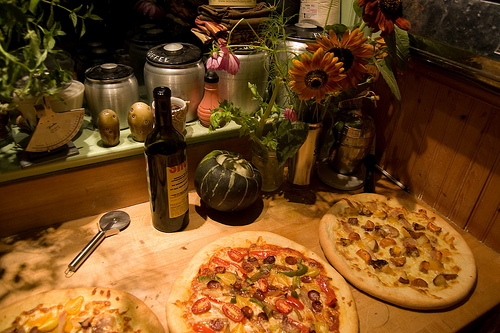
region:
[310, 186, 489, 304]
pizza on a counter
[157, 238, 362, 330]
pizza on a counter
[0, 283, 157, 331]
pizza on a counter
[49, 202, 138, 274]
pizza cutter on the counter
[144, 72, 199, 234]
bottle on the counter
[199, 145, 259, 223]
squash on the counter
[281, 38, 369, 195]
flowers in a vase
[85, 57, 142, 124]
canister on a ledge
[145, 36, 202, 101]
canister on a ledge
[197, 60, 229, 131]
pink bottle on a ledge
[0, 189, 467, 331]
Three pizzas on wooden surface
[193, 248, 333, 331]
Tomato toppings on pizza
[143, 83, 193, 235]
A green colored bottle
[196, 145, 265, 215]
Green pumpkin beside bottle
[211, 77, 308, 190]
A glass with plants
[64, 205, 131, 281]
Silver spoon on counter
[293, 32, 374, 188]
Sunflowers in a vase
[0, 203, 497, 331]
Brown counter made of wood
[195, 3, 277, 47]
Folded clothes on a vase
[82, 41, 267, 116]
Black and silver vases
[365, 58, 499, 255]
wood paneling on wall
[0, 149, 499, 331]
wooden counter-top touching walls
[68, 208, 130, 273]
a silver colored metal pizza cutter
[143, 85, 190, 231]
dark bottle with a label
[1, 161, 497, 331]
three cooked pizzas lined up on counter-top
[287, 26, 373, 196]
two large orange flowers in metal vase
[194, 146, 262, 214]
a dark green buttercup squash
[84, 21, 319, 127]
metal canisters on shelf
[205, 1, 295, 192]
pink flowers in a glass container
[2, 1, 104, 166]
green leafy plant up on shelf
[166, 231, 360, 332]
pizza with tomato and peppers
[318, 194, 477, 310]
pizza with sausage and mushrooms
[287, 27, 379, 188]
sunflowers in a silver vase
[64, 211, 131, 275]
metal pizza cutter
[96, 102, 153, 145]
ceramic salt and pepper shakers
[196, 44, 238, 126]
pink flowers in a coral vase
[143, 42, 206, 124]
silver food storage container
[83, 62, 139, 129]
silver food storage container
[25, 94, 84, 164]
food scale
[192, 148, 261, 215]
dark green gourd with light green stripes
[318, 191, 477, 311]
Pizza sitting on table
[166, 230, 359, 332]
Pizza sitting on table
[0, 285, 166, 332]
Pizza sitting on table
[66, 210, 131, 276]
Silver pizza cutter on table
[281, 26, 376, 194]
Silver flower vase with sunflowers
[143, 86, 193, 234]
Glass bottle on table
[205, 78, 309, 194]
Lettuce leafs in mason jar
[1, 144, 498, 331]
Wooden table with pizzas on it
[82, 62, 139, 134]
Silver and black container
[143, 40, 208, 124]
Silver and black container